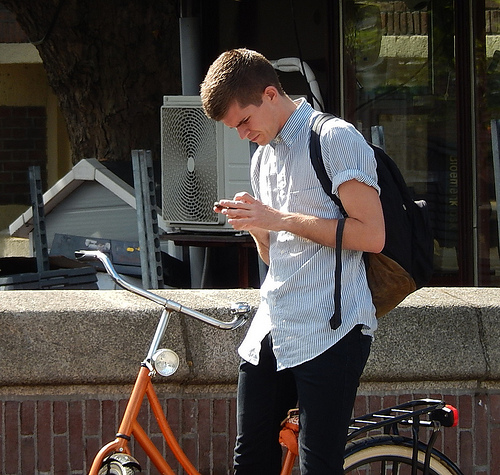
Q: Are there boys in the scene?
A: No, there are no boys.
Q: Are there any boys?
A: No, there are no boys.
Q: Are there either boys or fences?
A: No, there are no boys or fences.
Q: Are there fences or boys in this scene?
A: No, there are no boys or fences.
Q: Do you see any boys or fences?
A: No, there are no boys or fences.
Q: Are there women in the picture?
A: No, there are no women.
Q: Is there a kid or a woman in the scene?
A: No, there are no women or children.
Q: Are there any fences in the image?
A: No, there are no fences.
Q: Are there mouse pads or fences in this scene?
A: No, there are no fences or mouse pads.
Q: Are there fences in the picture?
A: No, there are no fences.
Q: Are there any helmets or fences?
A: No, there are no fences or helmets.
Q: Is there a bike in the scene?
A: Yes, there is a bike.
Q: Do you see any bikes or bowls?
A: Yes, there is a bike.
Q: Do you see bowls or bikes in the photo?
A: Yes, there is a bike.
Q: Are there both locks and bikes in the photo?
A: No, there is a bike but no locks.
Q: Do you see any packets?
A: No, there are no packets.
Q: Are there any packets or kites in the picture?
A: No, there are no packets or kites.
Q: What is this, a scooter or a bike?
A: This is a bike.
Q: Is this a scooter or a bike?
A: This is a bike.